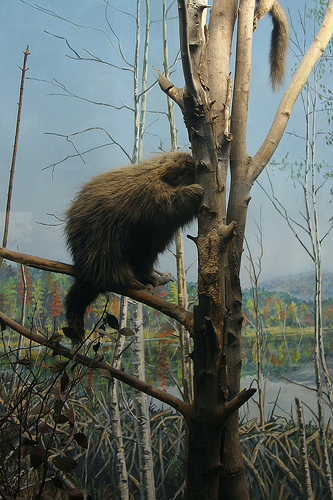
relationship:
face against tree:
[173, 153, 194, 186] [0, 0, 331, 498]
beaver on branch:
[57, 149, 210, 342] [1, 246, 191, 333]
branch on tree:
[1, 246, 191, 333] [0, 0, 331, 498]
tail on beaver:
[53, 275, 137, 352] [57, 149, 210, 342]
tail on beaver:
[267, 1, 290, 94] [252, 0, 291, 90]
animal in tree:
[51, 148, 227, 342] [0, 0, 331, 498]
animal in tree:
[254, 0, 288, 92] [0, 0, 331, 498]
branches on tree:
[2, 247, 197, 419] [0, 0, 331, 498]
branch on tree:
[0, 311, 193, 416] [0, 0, 331, 498]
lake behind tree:
[0, 330, 329, 426] [0, 0, 331, 498]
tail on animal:
[267, 1, 290, 94] [59, 148, 208, 342]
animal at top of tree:
[59, 148, 208, 342] [0, 0, 331, 498]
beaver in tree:
[42, 149, 235, 328] [127, 0, 319, 288]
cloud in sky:
[5, 15, 41, 46] [1, 0, 331, 286]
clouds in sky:
[10, 8, 287, 206] [1, 1, 331, 432]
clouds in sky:
[264, 181, 314, 265] [1, 0, 331, 286]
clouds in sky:
[0, 148, 332, 286] [1, 0, 331, 286]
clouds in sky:
[263, 174, 321, 259] [261, 208, 272, 227]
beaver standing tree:
[57, 149, 210, 342] [81, 1, 320, 472]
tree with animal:
[68, 10, 305, 498] [59, 148, 208, 342]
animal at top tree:
[51, 148, 227, 342] [168, 25, 332, 360]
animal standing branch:
[59, 148, 208, 342] [2, 238, 208, 329]